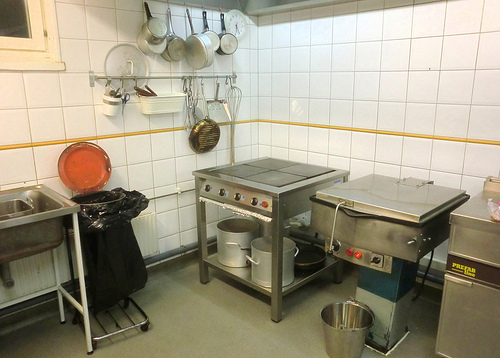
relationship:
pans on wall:
[109, 10, 233, 131] [74, 14, 263, 142]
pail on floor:
[298, 292, 408, 356] [87, 283, 406, 352]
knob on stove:
[364, 255, 395, 272] [292, 163, 470, 341]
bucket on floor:
[298, 292, 408, 356] [87, 283, 406, 352]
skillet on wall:
[187, 84, 220, 172] [74, 14, 263, 142]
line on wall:
[150, 113, 490, 150] [2, 4, 499, 136]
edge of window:
[1, 31, 77, 84] [3, 3, 86, 65]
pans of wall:
[109, 10, 233, 131] [2, 4, 499, 136]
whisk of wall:
[210, 69, 262, 125] [2, 4, 499, 136]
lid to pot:
[88, 33, 153, 91] [176, 12, 213, 71]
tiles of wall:
[323, 22, 467, 84] [2, 4, 499, 136]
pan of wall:
[187, 84, 220, 172] [2, 4, 499, 136]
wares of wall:
[74, 14, 263, 142] [2, 4, 499, 136]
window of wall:
[3, 3, 86, 65] [2, 4, 499, 136]